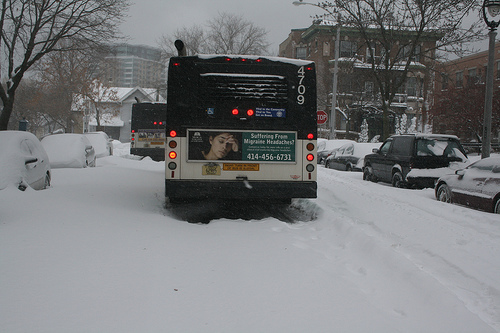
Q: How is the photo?
A: Clear.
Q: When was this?
A: Daytime.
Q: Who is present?
A: Nobody.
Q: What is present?
A: Snow.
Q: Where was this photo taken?
A: In the snow.